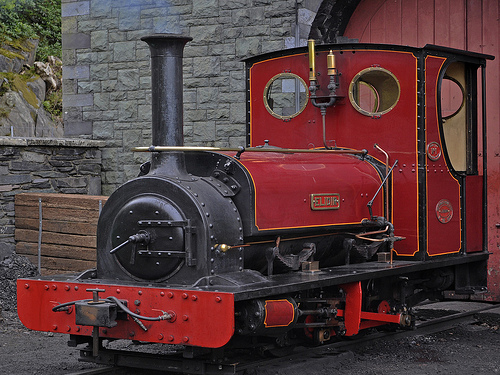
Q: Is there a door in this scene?
A: Yes, there is a door.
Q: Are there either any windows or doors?
A: Yes, there is a door.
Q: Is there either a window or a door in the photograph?
A: Yes, there is a door.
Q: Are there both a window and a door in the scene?
A: Yes, there are both a door and a window.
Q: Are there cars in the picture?
A: No, there are no cars.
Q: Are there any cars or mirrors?
A: No, there are no cars or mirrors.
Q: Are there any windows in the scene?
A: Yes, there is a window.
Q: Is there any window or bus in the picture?
A: Yes, there is a window.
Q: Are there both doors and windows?
A: Yes, there are both a window and a door.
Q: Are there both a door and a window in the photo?
A: Yes, there are both a window and a door.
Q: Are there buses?
A: No, there are no buses.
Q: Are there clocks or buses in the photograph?
A: No, there are no buses or clocks.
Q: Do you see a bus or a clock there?
A: No, there are no buses or clocks.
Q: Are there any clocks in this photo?
A: No, there are no clocks.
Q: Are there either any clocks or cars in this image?
A: No, there are no clocks or cars.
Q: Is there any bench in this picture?
A: Yes, there is a bench.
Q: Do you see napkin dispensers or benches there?
A: Yes, there is a bench.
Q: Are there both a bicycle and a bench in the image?
A: No, there is a bench but no bicycles.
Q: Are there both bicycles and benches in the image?
A: No, there is a bench but no bicycles.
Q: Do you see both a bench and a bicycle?
A: No, there is a bench but no bicycles.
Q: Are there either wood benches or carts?
A: Yes, there is a wood bench.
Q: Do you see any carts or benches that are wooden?
A: Yes, the bench is wooden.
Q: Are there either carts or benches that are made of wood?
A: Yes, the bench is made of wood.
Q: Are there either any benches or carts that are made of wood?
A: Yes, the bench is made of wood.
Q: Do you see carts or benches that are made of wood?
A: Yes, the bench is made of wood.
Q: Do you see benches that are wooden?
A: Yes, there is a wood bench.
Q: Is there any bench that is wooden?
A: Yes, there is a bench that is wooden.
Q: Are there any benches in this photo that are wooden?
A: Yes, there is a bench that is wooden.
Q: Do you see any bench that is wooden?
A: Yes, there is a bench that is wooden.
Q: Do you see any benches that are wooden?
A: Yes, there is a bench that is wooden.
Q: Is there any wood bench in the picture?
A: Yes, there is a bench that is made of wood.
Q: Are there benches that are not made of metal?
A: Yes, there is a bench that is made of wood.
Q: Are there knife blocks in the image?
A: No, there are no knife blocks.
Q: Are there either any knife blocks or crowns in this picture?
A: No, there are no knife blocks or crowns.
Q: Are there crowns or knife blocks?
A: No, there are no knife blocks or crowns.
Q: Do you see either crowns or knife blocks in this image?
A: No, there are no knife blocks or crowns.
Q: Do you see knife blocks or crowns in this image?
A: No, there are no knife blocks or crowns.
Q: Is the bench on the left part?
A: Yes, the bench is on the left of the image.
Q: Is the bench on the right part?
A: No, the bench is on the left of the image.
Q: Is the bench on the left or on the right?
A: The bench is on the left of the image.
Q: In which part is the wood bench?
A: The bench is on the left of the image.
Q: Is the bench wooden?
A: Yes, the bench is wooden.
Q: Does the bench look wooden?
A: Yes, the bench is wooden.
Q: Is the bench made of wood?
A: Yes, the bench is made of wood.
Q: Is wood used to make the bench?
A: Yes, the bench is made of wood.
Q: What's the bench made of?
A: The bench is made of wood.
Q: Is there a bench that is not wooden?
A: No, there is a bench but it is wooden.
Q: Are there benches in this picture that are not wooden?
A: No, there is a bench but it is wooden.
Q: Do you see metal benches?
A: No, there is a bench but it is made of wood.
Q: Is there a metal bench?
A: No, there is a bench but it is made of wood.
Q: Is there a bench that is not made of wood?
A: No, there is a bench but it is made of wood.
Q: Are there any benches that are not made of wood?
A: No, there is a bench but it is made of wood.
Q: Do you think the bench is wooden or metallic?
A: The bench is wooden.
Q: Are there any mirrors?
A: No, there are no mirrors.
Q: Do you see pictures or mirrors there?
A: No, there are no mirrors or pictures.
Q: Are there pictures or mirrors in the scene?
A: No, there are no mirrors or pictures.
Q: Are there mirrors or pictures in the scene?
A: No, there are no mirrors or pictures.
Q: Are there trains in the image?
A: Yes, there is a train.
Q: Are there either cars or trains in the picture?
A: Yes, there is a train.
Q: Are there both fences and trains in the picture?
A: No, there is a train but no fences.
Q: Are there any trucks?
A: No, there are no trucks.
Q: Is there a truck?
A: No, there are no trucks.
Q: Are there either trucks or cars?
A: No, there are no trucks or cars.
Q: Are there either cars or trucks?
A: No, there are no trucks or cars.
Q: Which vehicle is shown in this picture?
A: The vehicle is a train.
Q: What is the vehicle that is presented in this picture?
A: The vehicle is a train.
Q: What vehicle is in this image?
A: The vehicle is a train.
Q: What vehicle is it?
A: The vehicle is a train.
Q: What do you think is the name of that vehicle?
A: This is a train.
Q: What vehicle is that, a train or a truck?
A: This is a train.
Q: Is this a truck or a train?
A: This is a train.